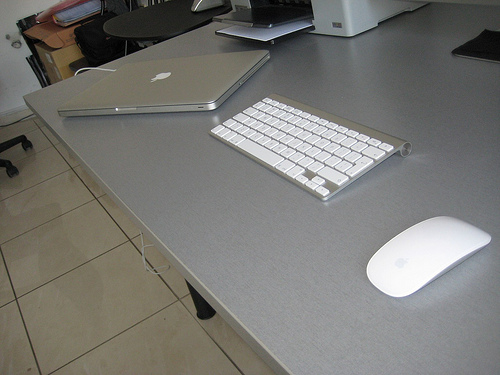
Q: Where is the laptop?
A: Table.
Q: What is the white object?
A: Mouse.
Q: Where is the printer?
A: Table.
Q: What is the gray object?
A: Table.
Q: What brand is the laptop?
A: Apple.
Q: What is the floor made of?
A: Tiles.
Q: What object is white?
A: Apple mouse.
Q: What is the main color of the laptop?
A: Gray.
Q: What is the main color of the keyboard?
A: White.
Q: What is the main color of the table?
A: Gray.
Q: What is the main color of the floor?
A: White.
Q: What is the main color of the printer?
A: White.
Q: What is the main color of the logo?
A: White.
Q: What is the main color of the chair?
A: Black.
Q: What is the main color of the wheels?
A: Black.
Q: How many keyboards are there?
A: One.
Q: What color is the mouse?
A: White.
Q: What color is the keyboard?
A: Silver and white.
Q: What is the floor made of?
A: Tile.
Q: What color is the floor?
A: Cream.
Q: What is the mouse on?
A: The table.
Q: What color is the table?
A: Silver.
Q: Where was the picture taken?
A: At an office at someone's desk.